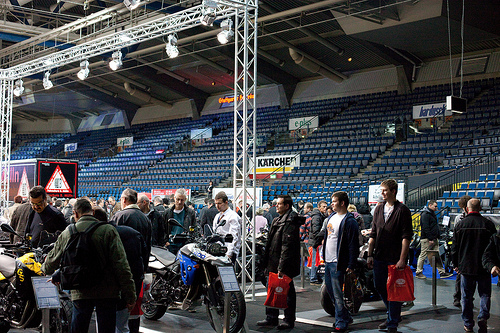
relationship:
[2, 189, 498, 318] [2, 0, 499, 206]
people in arena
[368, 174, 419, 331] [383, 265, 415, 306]
man carrying bag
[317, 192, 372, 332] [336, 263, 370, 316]
man carrying bag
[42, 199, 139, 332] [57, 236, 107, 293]
person has backpack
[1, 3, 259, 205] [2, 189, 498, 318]
structure above people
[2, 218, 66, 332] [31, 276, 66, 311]
motorcycle near sign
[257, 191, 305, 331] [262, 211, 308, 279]
man wearing jacket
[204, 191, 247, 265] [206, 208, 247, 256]
man wearing jacket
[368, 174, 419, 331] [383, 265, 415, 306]
man holding bag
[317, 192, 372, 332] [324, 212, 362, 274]
man wearing sweater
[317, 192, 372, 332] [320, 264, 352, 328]
man wearing jeans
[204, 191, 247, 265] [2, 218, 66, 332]
man looking at motorcycle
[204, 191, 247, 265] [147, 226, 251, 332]
man looking at bike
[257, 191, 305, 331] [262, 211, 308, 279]
man wears jacket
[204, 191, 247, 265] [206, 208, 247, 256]
man wears jacket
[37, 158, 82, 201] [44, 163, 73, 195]
sign has triangle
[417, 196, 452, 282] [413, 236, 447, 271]
man wears khakis